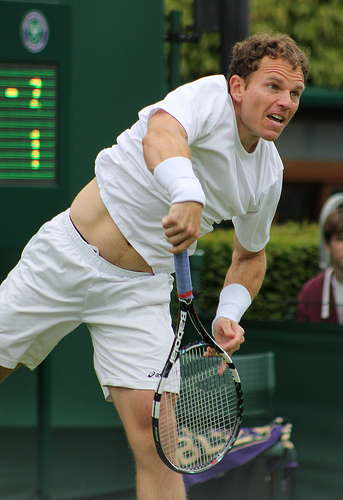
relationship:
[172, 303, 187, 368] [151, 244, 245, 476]
name on racket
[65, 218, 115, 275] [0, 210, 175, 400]
band on shorts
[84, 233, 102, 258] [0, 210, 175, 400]
string on shorts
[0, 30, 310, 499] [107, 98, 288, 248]
man with shirt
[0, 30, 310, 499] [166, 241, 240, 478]
man with racket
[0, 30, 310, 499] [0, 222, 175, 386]
man with shorts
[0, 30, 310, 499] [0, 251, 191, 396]
man with shorts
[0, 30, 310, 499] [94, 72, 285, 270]
man with shirt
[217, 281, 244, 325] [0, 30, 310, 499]
band on man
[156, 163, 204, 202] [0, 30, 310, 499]
band on man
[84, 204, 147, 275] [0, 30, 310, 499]
belly on man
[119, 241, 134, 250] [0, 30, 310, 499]
button on man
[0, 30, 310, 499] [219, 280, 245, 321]
man has band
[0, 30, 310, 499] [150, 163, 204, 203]
man has band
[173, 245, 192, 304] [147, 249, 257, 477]
handle on racket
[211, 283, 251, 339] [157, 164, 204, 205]
band on wrist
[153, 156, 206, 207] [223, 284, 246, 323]
band on wrist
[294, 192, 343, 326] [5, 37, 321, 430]
man watching game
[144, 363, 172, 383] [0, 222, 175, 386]
logo on shorts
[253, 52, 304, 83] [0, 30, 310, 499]
forhead on man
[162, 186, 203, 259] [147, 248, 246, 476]
hand with racket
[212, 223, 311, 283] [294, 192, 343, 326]
hedges behind man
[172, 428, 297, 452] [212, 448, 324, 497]
banner on ground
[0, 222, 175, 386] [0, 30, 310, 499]
shorts on man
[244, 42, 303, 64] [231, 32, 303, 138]
hair on head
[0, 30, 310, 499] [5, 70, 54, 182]
man front of scoreboard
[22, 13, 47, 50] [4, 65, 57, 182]
logo above scoreboard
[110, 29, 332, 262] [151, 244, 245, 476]
man playing racket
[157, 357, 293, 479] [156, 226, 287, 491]
strings on racket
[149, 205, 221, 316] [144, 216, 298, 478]
handle on racket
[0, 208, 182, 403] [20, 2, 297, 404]
shorts on player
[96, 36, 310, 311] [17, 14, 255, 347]
shirt on player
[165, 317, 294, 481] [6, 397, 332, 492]
chair next to court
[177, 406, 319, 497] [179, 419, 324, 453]
towel with lettering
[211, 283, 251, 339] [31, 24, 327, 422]
band of player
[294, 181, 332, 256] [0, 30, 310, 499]
man watching man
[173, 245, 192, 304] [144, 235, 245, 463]
handle on raquet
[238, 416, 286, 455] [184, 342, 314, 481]
towel on chair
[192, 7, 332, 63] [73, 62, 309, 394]
hedges behind player